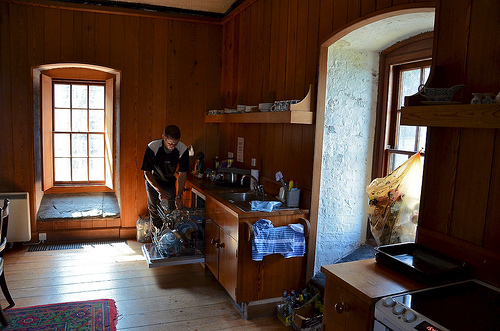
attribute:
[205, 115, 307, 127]
cupboard — wooden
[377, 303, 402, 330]
stove — smooth, modern, white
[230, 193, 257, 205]
sink — steel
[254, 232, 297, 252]
towel — white, blue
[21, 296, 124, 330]
rug — multicolored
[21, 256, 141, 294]
floor — wooden